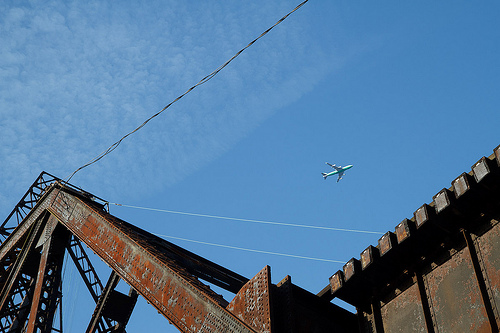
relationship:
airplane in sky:
[320, 162, 354, 183] [182, 1, 457, 263]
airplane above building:
[314, 158, 356, 182] [0, 140, 500, 332]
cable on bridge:
[80, 59, 220, 197] [1, 142, 484, 331]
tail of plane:
[315, 170, 329, 185] [309, 150, 356, 182]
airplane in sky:
[320, 162, 354, 183] [281, 51, 426, 131]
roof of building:
[326, 198, 493, 290] [324, 150, 499, 330]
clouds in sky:
[17, 9, 291, 134] [0, 0, 492, 331]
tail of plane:
[319, 172, 327, 181] [312, 155, 357, 184]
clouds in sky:
[17, 9, 291, 134] [1, 2, 492, 289]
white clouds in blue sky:
[0, 0, 320, 196] [1, 1, 498, 331]